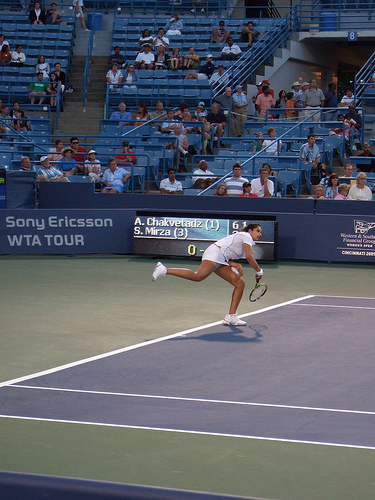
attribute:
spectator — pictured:
[100, 157, 134, 195]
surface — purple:
[3, 293, 373, 455]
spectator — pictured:
[199, 105, 270, 156]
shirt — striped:
[224, 175, 248, 194]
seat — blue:
[239, 158, 255, 175]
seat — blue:
[280, 169, 299, 185]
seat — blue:
[212, 168, 229, 177]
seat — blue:
[219, 149, 236, 158]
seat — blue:
[289, 138, 301, 153]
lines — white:
[83, 382, 212, 444]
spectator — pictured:
[246, 165, 278, 197]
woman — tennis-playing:
[150, 222, 268, 327]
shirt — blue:
[56, 159, 75, 170]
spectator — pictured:
[192, 157, 218, 191]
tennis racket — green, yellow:
[249, 267, 268, 305]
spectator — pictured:
[159, 166, 183, 193]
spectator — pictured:
[307, 184, 328, 199]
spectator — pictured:
[221, 163, 249, 197]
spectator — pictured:
[346, 170, 372, 199]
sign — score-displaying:
[132, 214, 234, 242]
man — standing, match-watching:
[302, 77, 325, 122]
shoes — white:
[152, 261, 165, 280]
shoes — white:
[221, 314, 244, 324]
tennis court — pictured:
[3, 286, 372, 451]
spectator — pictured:
[239, 181, 256, 195]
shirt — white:
[160, 177, 184, 189]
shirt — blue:
[300, 145, 321, 156]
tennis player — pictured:
[151, 218, 266, 327]